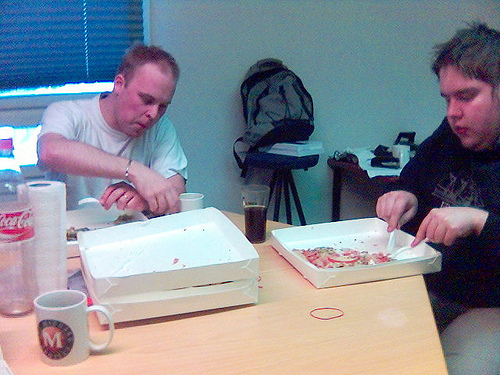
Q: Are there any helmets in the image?
A: No, there are no helmets.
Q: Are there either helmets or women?
A: No, there are no helmets or women.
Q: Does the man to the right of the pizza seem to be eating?
A: Yes, the man is eating.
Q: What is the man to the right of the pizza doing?
A: The man is eating.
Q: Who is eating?
A: The man is eating.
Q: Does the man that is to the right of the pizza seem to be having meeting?
A: No, the man is eating.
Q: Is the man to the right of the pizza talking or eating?
A: The man is eating.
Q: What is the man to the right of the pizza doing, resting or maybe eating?
A: The man is eating.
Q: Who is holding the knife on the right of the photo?
A: The man is holding the knife.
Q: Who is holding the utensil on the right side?
A: The man is holding the knife.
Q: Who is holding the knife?
A: The man is holding the knife.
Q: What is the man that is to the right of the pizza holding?
A: The man is holding the knife.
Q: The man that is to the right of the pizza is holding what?
A: The man is holding the knife.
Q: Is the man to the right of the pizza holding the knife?
A: Yes, the man is holding the knife.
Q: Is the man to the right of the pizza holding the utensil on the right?
A: Yes, the man is holding the knife.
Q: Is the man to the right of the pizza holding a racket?
A: No, the man is holding the knife.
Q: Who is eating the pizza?
A: The man is eating the pizza.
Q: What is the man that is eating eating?
A: The man is eating a pizza.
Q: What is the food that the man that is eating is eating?
A: The food is a pizza.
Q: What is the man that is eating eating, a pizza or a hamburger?
A: The man is eating a pizza.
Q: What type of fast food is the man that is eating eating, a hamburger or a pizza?
A: The man is eating a pizza.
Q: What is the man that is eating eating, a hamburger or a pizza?
A: The man is eating a pizza.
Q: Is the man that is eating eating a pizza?
A: Yes, the man is eating a pizza.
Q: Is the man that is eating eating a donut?
A: No, the man is eating a pizza.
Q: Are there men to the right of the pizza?
A: Yes, there is a man to the right of the pizza.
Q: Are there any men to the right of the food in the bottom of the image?
A: Yes, there is a man to the right of the pizza.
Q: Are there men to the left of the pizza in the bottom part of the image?
A: No, the man is to the right of the pizza.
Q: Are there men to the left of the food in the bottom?
A: No, the man is to the right of the pizza.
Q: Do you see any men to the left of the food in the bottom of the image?
A: No, the man is to the right of the pizza.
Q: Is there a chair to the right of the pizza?
A: No, there is a man to the right of the pizza.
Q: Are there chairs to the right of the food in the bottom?
A: No, there is a man to the right of the pizza.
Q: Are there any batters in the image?
A: No, there are no batters.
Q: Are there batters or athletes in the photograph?
A: No, there are no batters or athletes.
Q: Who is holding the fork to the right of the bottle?
A: The man is holding the fork.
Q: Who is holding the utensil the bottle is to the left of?
A: The man is holding the fork.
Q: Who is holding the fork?
A: The man is holding the fork.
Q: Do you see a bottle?
A: Yes, there is a bottle.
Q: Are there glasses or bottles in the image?
A: Yes, there is a bottle.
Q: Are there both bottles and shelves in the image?
A: No, there is a bottle but no shelves.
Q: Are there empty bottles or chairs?
A: Yes, there is an empty bottle.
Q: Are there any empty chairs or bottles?
A: Yes, there is an empty bottle.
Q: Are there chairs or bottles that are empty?
A: Yes, the bottle is empty.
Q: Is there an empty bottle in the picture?
A: Yes, there is an empty bottle.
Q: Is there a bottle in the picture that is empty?
A: Yes, there is a bottle that is empty.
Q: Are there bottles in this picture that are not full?
A: Yes, there is a empty bottle.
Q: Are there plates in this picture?
A: No, there are no plates.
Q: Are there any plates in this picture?
A: No, there are no plates.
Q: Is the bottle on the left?
A: Yes, the bottle is on the left of the image.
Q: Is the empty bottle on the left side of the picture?
A: Yes, the bottle is on the left of the image.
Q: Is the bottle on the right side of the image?
A: No, the bottle is on the left of the image.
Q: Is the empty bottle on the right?
A: No, the bottle is on the left of the image.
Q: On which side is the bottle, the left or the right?
A: The bottle is on the left of the image.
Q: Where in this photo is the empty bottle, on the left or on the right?
A: The bottle is on the left of the image.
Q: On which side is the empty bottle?
A: The bottle is on the left of the image.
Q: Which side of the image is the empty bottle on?
A: The bottle is on the left of the image.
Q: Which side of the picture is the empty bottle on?
A: The bottle is on the left of the image.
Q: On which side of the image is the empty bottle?
A: The bottle is on the left of the image.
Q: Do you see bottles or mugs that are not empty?
A: No, there is a bottle but it is empty.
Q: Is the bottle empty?
A: Yes, the bottle is empty.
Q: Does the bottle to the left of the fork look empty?
A: Yes, the bottle is empty.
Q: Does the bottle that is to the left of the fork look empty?
A: Yes, the bottle is empty.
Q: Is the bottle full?
A: No, the bottle is empty.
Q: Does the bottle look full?
A: No, the bottle is empty.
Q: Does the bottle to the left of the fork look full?
A: No, the bottle is empty.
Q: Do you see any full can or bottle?
A: No, there is a bottle but it is empty.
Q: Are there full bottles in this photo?
A: No, there is a bottle but it is empty.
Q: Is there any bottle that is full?
A: No, there is a bottle but it is empty.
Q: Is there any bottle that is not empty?
A: No, there is a bottle but it is empty.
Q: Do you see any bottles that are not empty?
A: No, there is a bottle but it is empty.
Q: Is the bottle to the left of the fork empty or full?
A: The bottle is empty.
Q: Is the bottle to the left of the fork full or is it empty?
A: The bottle is empty.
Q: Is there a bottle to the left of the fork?
A: Yes, there is a bottle to the left of the fork.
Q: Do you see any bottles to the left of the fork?
A: Yes, there is a bottle to the left of the fork.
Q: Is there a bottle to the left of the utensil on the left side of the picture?
A: Yes, there is a bottle to the left of the fork.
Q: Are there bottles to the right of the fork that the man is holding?
A: No, the bottle is to the left of the fork.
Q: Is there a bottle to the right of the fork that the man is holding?
A: No, the bottle is to the left of the fork.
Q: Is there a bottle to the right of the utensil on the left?
A: No, the bottle is to the left of the fork.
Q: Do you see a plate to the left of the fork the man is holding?
A: No, there is a bottle to the left of the fork.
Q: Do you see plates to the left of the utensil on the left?
A: No, there is a bottle to the left of the fork.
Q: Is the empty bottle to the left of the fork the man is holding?
A: Yes, the bottle is to the left of the fork.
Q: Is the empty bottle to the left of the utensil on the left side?
A: Yes, the bottle is to the left of the fork.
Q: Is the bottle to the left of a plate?
A: No, the bottle is to the left of the fork.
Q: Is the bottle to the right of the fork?
A: No, the bottle is to the left of the fork.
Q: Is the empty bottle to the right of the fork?
A: No, the bottle is to the left of the fork.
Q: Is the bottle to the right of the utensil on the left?
A: No, the bottle is to the left of the fork.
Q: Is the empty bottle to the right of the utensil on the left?
A: No, the bottle is to the left of the fork.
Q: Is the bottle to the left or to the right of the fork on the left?
A: The bottle is to the left of the fork.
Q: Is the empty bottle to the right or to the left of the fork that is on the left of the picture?
A: The bottle is to the left of the fork.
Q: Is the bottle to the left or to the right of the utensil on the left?
A: The bottle is to the left of the fork.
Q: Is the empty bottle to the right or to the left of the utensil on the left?
A: The bottle is to the left of the fork.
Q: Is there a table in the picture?
A: Yes, there is a table.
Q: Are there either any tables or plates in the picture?
A: Yes, there is a table.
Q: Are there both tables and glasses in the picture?
A: No, there is a table but no glasses.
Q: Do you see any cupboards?
A: No, there are no cupboards.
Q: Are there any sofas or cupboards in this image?
A: No, there are no cupboards or sofas.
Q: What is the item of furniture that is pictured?
A: The piece of furniture is a table.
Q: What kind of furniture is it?
A: The piece of furniture is a table.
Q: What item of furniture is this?
A: This is a table.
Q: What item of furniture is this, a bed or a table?
A: This is a table.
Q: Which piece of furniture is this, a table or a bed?
A: This is a table.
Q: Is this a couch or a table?
A: This is a table.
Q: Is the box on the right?
A: Yes, the box is on the right of the image.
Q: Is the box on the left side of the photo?
A: No, the box is on the right of the image.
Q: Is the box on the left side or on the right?
A: The box is on the right of the image.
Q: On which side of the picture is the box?
A: The box is on the right of the image.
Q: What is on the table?
A: The box is on the table.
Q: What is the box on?
A: The box is on the table.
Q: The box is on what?
A: The box is on the table.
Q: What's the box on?
A: The box is on the table.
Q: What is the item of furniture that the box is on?
A: The piece of furniture is a table.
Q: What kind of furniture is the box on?
A: The box is on the table.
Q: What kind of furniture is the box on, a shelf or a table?
A: The box is on a table.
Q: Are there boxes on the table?
A: Yes, there is a box on the table.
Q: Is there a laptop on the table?
A: No, there is a box on the table.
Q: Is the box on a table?
A: Yes, the box is on a table.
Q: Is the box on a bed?
A: No, the box is on a table.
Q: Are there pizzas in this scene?
A: Yes, there is a pizza.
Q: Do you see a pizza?
A: Yes, there is a pizza.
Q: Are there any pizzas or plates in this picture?
A: Yes, there is a pizza.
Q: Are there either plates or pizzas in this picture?
A: Yes, there is a pizza.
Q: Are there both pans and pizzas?
A: No, there is a pizza but no pans.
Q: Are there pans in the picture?
A: No, there are no pans.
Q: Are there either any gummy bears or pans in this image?
A: No, there are no pans or gummy bears.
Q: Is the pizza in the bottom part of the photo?
A: Yes, the pizza is in the bottom of the image.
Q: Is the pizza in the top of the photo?
A: No, the pizza is in the bottom of the image.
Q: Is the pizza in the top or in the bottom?
A: The pizza is in the bottom of the image.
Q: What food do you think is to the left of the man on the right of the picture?
A: The food is a pizza.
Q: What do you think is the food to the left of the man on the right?
A: The food is a pizza.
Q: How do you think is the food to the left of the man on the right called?
A: The food is a pizza.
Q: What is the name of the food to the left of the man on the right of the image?
A: The food is a pizza.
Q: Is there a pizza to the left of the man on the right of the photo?
A: Yes, there is a pizza to the left of the man.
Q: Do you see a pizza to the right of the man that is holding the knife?
A: No, the pizza is to the left of the man.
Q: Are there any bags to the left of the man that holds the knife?
A: No, there is a pizza to the left of the man.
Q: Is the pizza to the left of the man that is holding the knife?
A: Yes, the pizza is to the left of the man.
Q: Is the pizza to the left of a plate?
A: No, the pizza is to the left of the man.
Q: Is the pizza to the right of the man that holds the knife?
A: No, the pizza is to the left of the man.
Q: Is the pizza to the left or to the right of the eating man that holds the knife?
A: The pizza is to the left of the man.